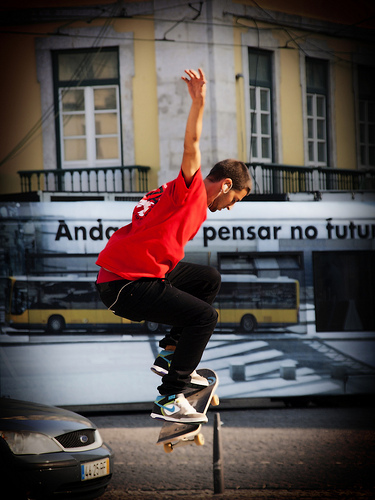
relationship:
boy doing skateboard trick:
[94, 65, 257, 425] [140, 351, 234, 492]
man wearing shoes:
[92, 63, 264, 451] [147, 347, 211, 426]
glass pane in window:
[61, 113, 86, 134] [55, 83, 123, 166]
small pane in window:
[95, 111, 119, 136] [55, 83, 123, 166]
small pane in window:
[93, 135, 121, 158] [55, 83, 123, 166]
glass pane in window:
[61, 90, 85, 112] [55, 83, 123, 166]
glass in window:
[96, 135, 120, 161] [48, 45, 125, 190]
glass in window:
[248, 87, 256, 110] [248, 85, 275, 162]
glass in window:
[260, 87, 270, 112] [248, 85, 275, 162]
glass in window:
[258, 111, 271, 136] [248, 85, 275, 162]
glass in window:
[261, 134, 271, 159] [248, 85, 275, 162]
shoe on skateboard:
[150, 392, 209, 424] [154, 367, 220, 451]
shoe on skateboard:
[151, 347, 210, 388] [154, 367, 220, 451]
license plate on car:
[80, 456, 110, 481] [0, 395, 116, 498]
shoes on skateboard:
[150, 349, 208, 425] [154, 367, 220, 451]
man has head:
[95, 67, 253, 425] [203, 157, 250, 212]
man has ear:
[95, 67, 253, 425] [220, 177, 232, 194]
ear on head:
[220, 177, 232, 194] [203, 157, 250, 212]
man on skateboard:
[95, 67, 253, 425] [154, 367, 220, 451]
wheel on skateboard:
[162, 440, 174, 453] [154, 367, 220, 451]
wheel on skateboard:
[195, 434, 206, 447] [154, 367, 220, 451]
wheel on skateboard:
[211, 394, 220, 407] [154, 367, 220, 451]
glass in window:
[89, 86, 119, 111] [55, 83, 123, 166]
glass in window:
[316, 95, 326, 118] [302, 91, 329, 165]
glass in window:
[317, 117, 325, 139] [302, 91, 329, 165]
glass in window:
[317, 140, 327, 163] [302, 91, 329, 165]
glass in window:
[306, 116, 315, 139] [302, 91, 329, 165]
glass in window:
[305, 95, 315, 116] [303, 91, 331, 166]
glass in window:
[261, 112, 271, 137] [244, 84, 276, 163]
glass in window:
[260, 136, 271, 160] [244, 84, 276, 163]